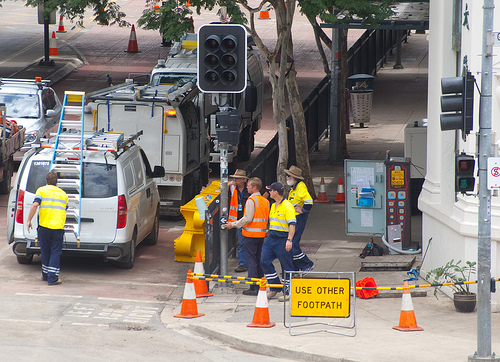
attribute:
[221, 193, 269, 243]
vest — orange, reflective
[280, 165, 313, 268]
men — four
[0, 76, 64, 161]
car — silver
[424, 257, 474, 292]
plant — green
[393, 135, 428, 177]
ground — orange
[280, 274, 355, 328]
yellow sign — black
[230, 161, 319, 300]
workers — construction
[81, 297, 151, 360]
road — part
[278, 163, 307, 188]
worker — bushy, white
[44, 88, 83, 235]
ladder — blue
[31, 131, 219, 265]
van — white, utiity 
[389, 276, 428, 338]
traffic cone — orange, white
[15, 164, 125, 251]
white van — back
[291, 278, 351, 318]
sign — yellow, black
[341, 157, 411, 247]
utility box — open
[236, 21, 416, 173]
fencing — black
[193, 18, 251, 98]
trafic light — non-working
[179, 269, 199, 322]
cone — four, orange, white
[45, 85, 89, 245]
blue/yellow ladder — blue, yellow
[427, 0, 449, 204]
wall — white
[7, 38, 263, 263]
vehicles — close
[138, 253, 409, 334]
cones — orange, white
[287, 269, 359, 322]
warning sign — yellow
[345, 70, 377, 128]
can — small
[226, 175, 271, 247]
vest — orange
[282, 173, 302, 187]
beard — white